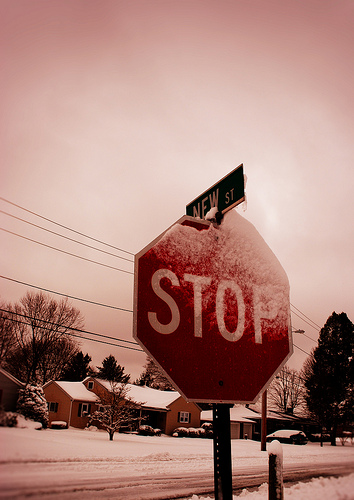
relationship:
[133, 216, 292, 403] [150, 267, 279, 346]
sign says stop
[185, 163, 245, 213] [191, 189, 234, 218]
sign says new st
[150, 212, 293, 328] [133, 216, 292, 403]
snow covering sign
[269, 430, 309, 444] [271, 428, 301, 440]
car covered in snow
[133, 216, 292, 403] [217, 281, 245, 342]
sign has a letter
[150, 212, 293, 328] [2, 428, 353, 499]
snow covering ground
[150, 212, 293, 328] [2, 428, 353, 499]
snow on ground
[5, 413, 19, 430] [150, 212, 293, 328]
bush has snow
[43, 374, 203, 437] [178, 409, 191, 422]
house has a window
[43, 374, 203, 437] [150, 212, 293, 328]
house covered in snow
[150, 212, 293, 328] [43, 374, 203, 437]
snow on a house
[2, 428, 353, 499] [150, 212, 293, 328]
ground has snow